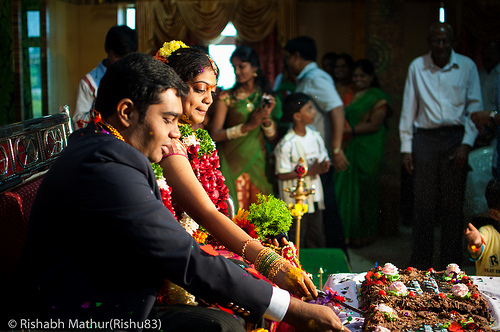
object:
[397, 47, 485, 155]
shirt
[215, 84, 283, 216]
dress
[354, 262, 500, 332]
cake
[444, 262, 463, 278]
flowers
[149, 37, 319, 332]
lady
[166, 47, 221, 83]
hair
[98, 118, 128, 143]
necklace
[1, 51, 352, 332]
man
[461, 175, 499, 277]
boy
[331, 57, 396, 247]
lady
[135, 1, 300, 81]
curtain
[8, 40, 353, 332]
couple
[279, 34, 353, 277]
guests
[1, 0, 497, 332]
reception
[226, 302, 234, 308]
cuff links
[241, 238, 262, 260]
bracelets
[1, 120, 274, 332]
suit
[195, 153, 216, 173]
flowers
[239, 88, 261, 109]
necklace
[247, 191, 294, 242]
bush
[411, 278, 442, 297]
writing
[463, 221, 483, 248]
hand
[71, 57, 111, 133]
jacket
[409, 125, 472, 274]
pants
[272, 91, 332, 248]
child